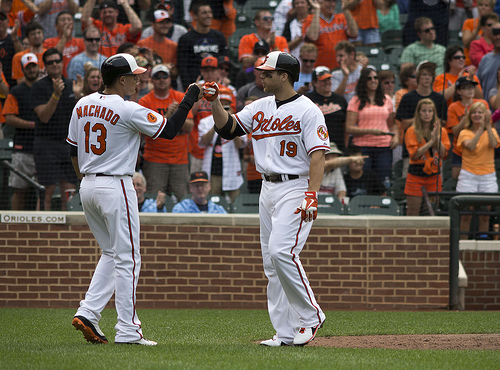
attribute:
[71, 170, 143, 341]
pants — white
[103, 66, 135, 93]
head — man's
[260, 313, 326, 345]
cleats — white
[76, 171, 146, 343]
pants — white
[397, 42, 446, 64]
shirt — green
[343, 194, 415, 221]
chair — pictured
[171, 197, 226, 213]
shirt — blue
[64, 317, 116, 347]
cleat — black, orange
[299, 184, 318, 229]
glove — red, white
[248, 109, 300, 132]
name — print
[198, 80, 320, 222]
gloves — orange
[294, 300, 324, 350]
cleat — white, orange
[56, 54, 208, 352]
player — baseball player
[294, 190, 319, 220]
glove — orange, white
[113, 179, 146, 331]
stripe — orange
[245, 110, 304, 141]
orioles print — large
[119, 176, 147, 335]
stripe — red